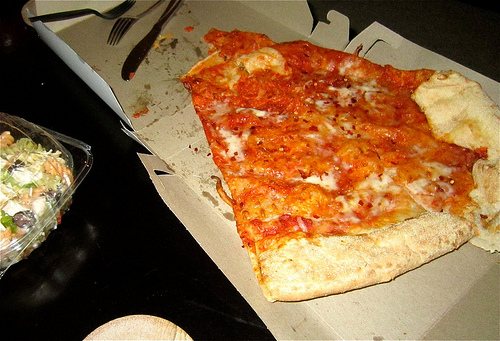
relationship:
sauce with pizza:
[194, 27, 479, 222] [192, 22, 497, 300]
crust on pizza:
[246, 227, 463, 285] [187, 24, 450, 209]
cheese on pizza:
[181, 26, 487, 251] [192, 22, 497, 300]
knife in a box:
[117, 2, 184, 82] [28, 0, 498, 340]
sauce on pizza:
[253, 62, 391, 188] [170, 40, 466, 312]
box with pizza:
[20, 0, 497, 340] [168, 21, 466, 323]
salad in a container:
[1, 130, 68, 248] [0, 110, 91, 279]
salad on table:
[1, 130, 68, 248] [2, 1, 274, 338]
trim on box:
[31, 16, 131, 127] [75, 41, 249, 191]